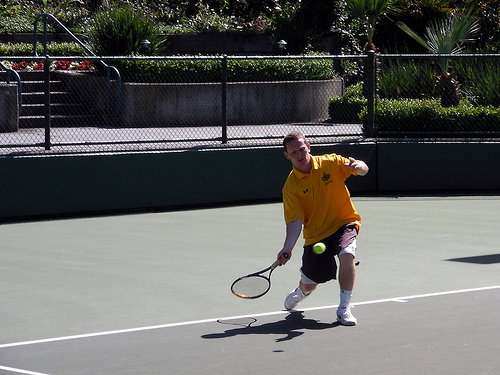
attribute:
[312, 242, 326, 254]
ball — green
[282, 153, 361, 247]
shirt — yellow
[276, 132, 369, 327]
man — holding, playing, hitting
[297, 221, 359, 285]
shorts — brown, black, white, maroon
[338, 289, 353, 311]
sock — white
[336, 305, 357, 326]
shoe — white, black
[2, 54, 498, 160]
fence — black, metal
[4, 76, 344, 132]
wall — concrete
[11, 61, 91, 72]
flowers — red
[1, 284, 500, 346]
line — white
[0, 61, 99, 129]
stair — concrete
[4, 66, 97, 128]
stairs — black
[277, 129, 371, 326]
player — amateur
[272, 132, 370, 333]
player — amateur